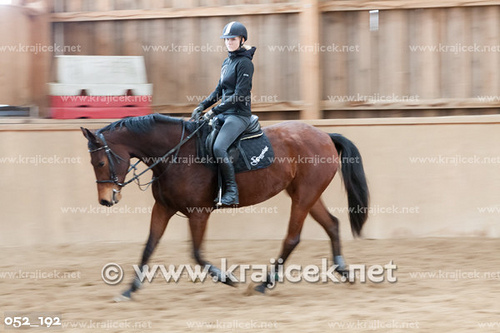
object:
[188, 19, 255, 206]
girl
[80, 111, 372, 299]
horse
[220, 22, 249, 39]
helmet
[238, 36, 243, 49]
strip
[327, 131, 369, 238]
tail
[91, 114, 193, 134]
mane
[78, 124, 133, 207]
head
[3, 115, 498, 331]
floor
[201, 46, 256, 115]
jacket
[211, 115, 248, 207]
left leg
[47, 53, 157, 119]
cooler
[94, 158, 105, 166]
eye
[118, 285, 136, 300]
hoof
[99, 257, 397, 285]
watermark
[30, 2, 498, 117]
fence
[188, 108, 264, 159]
saddle